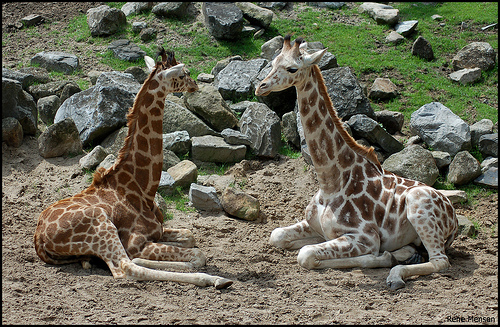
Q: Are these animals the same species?
A: Yes, all the animals are giraffes.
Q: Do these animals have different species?
A: No, all the animals are giraffes.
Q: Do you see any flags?
A: No, there are no flags.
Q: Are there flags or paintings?
A: No, there are no flags or paintings.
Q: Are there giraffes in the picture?
A: Yes, there is a giraffe.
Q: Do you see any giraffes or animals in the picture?
A: Yes, there is a giraffe.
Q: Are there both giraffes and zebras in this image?
A: No, there is a giraffe but no zebras.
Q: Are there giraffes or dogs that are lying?
A: Yes, the giraffe is lying.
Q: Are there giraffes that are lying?
A: Yes, there is a giraffe that is lying.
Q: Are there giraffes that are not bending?
A: Yes, there is a giraffe that is lying.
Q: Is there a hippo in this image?
A: No, there are no hippos.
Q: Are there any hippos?
A: No, there are no hippos.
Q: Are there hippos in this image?
A: No, there are no hippos.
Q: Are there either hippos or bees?
A: No, there are no hippos or bees.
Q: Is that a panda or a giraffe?
A: That is a giraffe.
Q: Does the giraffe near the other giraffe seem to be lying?
A: Yes, the giraffe is lying.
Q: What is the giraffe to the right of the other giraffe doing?
A: The giraffe is lying.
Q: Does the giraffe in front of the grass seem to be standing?
A: No, the giraffe is lying.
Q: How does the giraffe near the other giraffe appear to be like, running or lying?
A: The giraffe is lying.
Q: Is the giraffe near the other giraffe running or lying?
A: The giraffe is lying.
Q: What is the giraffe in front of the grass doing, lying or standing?
A: The giraffe is lying.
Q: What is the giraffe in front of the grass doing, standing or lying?
A: The giraffe is lying.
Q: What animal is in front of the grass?
A: The animal is a giraffe.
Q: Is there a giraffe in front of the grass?
A: Yes, there is a giraffe in front of the grass.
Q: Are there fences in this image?
A: No, there are no fences.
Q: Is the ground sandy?
A: Yes, the ground is sandy.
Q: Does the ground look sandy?
A: Yes, the ground is sandy.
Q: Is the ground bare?
A: No, the ground is sandy.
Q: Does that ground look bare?
A: No, the ground is sandy.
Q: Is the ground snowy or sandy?
A: The ground is sandy.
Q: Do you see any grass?
A: Yes, there is grass.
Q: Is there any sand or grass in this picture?
A: Yes, there is grass.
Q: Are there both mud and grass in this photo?
A: No, there is grass but no mud.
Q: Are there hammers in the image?
A: No, there are no hammers.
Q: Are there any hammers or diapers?
A: No, there are no hammers or diapers.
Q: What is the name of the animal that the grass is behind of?
A: The animal is a giraffe.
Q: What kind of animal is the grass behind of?
A: The grass is behind the giraffe.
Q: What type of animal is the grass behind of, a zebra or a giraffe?
A: The grass is behind a giraffe.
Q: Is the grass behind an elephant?
A: No, the grass is behind the giraffe.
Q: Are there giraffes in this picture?
A: Yes, there is a giraffe.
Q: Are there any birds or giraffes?
A: Yes, there is a giraffe.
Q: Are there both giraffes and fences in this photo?
A: No, there is a giraffe but no fences.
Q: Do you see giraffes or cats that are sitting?
A: Yes, the giraffe is sitting.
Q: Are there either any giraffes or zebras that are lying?
A: Yes, the giraffe is lying.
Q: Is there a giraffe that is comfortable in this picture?
A: Yes, there is a comfortable giraffe.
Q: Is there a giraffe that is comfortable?
A: Yes, there is a giraffe that is comfortable.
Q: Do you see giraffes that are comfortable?
A: Yes, there is a giraffe that is comfortable.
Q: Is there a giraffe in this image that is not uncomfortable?
A: Yes, there is an comfortable giraffe.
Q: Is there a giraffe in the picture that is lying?
A: Yes, there is a giraffe that is lying.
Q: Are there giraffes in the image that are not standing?
A: Yes, there is a giraffe that is lying.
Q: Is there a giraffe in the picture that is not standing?
A: Yes, there is a giraffe that is lying.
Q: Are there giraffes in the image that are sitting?
A: Yes, there is a giraffe that is sitting.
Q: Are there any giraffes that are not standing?
A: Yes, there is a giraffe that is sitting.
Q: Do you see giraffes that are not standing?
A: Yes, there is a giraffe that is sitting .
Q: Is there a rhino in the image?
A: No, there are no rhinos.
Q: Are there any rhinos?
A: No, there are no rhinos.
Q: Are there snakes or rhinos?
A: No, there are no rhinos or snakes.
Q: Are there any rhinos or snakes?
A: No, there are no rhinos or snakes.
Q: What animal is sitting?
A: The animal is a giraffe.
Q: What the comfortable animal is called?
A: The animal is a giraffe.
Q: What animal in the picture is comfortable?
A: The animal is a giraffe.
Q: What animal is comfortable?
A: The animal is a giraffe.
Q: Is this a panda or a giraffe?
A: This is a giraffe.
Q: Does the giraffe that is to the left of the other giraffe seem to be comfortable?
A: Yes, the giraffe is comfortable.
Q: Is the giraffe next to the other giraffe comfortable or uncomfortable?
A: The giraffe is comfortable.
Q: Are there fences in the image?
A: No, there are no fences.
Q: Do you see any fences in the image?
A: No, there are no fences.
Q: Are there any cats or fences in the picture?
A: No, there are no fences or cats.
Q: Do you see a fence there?
A: No, there are no fences.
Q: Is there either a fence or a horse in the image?
A: No, there are no fences or horses.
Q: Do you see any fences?
A: No, there are no fences.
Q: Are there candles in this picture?
A: No, there are no candles.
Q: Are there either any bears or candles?
A: No, there are no candles or bears.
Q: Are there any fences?
A: No, there are no fences.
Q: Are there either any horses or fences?
A: No, there are no fences or horses.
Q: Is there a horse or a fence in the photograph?
A: No, there are no fences or horses.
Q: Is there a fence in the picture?
A: No, there are no fences.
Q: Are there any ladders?
A: No, there are no ladders.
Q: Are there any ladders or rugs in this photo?
A: No, there are no ladders or rugs.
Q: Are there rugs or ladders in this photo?
A: No, there are no ladders or rugs.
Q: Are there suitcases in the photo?
A: No, there are no suitcases.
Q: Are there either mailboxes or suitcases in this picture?
A: No, there are no suitcases or mailboxes.